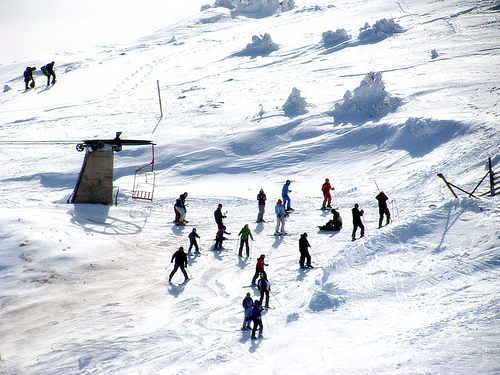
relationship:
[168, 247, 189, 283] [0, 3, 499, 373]
person on snow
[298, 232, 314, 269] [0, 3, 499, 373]
person on snow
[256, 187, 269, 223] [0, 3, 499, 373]
skier on snow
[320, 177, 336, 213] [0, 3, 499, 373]
skier on snow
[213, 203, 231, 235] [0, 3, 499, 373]
person on snow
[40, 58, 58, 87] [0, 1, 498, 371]
person walking up hill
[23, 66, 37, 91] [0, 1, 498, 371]
people walking up hill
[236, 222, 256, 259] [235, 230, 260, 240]
person wearing jacket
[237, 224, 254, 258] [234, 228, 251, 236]
person wearing jacket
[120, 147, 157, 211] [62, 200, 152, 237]
lift casting shadow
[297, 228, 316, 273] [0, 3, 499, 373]
person skiing on snow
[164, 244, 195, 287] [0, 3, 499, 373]
person skiing on snow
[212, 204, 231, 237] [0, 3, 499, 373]
person skiing on snow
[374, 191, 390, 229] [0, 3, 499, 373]
people skiing on snow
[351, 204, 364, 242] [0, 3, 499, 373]
people skiing on snow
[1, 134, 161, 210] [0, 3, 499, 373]
ski lift over snow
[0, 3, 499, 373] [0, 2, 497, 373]
snow covering ground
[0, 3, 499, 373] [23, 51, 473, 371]
snow on ground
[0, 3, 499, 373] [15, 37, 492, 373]
snow on ground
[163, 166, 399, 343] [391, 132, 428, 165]
people on ground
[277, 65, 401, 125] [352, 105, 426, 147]
bergs on snow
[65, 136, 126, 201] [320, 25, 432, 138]
stone on snow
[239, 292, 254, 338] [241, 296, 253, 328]
skier wears blue outifit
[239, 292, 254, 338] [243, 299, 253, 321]
skier wears black outifit